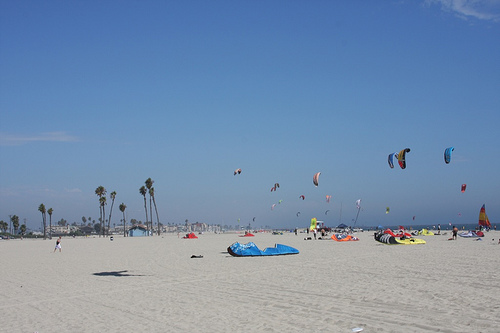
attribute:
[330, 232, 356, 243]
structure — orange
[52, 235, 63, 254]
person — nice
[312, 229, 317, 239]
person — nice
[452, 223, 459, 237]
person — nice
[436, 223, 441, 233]
person — nice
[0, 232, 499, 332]
beach — nice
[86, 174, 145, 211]
trees — green, palm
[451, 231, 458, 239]
shorts — black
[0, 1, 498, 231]
sky — clear